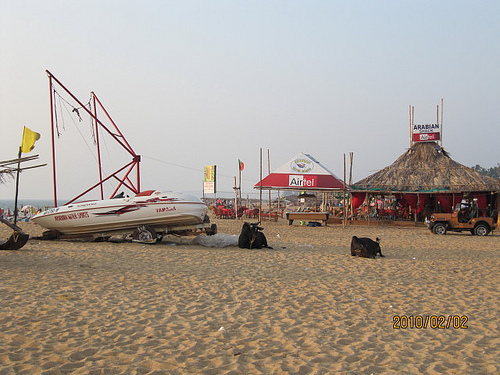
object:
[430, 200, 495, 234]
vehicle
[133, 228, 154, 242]
wheel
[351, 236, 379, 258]
bag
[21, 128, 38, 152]
flag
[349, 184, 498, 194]
edge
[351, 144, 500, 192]
roof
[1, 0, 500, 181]
sky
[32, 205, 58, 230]
front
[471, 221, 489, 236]
wheel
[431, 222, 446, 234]
wheel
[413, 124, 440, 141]
banner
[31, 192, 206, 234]
boat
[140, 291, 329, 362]
sand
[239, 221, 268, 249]
cow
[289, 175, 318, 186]
sign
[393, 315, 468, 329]
date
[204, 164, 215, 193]
sign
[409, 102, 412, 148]
poles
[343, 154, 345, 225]
poles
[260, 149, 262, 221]
poles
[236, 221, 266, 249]
motor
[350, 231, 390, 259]
motor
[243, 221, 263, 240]
head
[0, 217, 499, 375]
bench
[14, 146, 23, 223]
pole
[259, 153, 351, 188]
tent